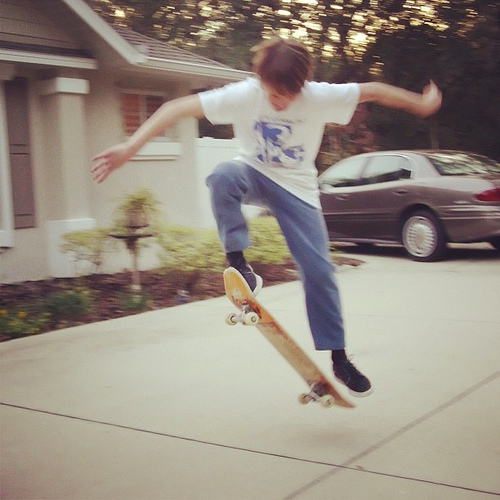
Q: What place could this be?
A: It is a sidewalk.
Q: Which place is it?
A: It is a sidewalk.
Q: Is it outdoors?
A: Yes, it is outdoors.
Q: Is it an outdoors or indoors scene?
A: It is outdoors.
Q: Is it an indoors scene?
A: No, it is outdoors.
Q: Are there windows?
A: Yes, there is a window.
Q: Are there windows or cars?
A: Yes, there is a window.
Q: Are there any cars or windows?
A: Yes, there is a window.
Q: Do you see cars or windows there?
A: Yes, there is a window.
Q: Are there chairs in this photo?
A: No, there are no chairs.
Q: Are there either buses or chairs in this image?
A: No, there are no chairs or buses.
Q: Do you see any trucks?
A: No, there are no trucks.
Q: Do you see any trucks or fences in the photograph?
A: No, there are no trucks or fences.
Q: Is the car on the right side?
A: Yes, the car is on the right of the image.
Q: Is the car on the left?
A: No, the car is on the right of the image.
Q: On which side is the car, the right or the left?
A: The car is on the right of the image.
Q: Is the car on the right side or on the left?
A: The car is on the right of the image.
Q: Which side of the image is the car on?
A: The car is on the right of the image.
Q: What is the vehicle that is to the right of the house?
A: The vehicle is a car.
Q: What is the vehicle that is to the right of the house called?
A: The vehicle is a car.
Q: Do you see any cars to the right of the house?
A: Yes, there is a car to the right of the house.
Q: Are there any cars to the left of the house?
A: No, the car is to the right of the house.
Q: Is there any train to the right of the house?
A: No, there is a car to the right of the house.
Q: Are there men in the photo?
A: No, there are no men.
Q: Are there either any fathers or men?
A: No, there are no men or fathers.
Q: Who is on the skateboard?
A: The boy is on the skateboard.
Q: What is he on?
A: The boy is on the skateboard.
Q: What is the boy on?
A: The boy is on the skateboard.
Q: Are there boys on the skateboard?
A: Yes, there is a boy on the skateboard.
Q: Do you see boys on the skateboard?
A: Yes, there is a boy on the skateboard.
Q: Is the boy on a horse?
A: No, the boy is on the skateboard.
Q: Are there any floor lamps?
A: No, there are no floor lamps.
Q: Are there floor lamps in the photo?
A: No, there are no floor lamps.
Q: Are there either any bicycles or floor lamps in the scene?
A: No, there are no floor lamps or bicycles.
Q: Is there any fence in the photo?
A: No, there are no fences.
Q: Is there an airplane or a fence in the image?
A: No, there are no fences or airplanes.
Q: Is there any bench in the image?
A: No, there are no benches.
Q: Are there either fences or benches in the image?
A: No, there are no benches or fences.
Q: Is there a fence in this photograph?
A: No, there are no fences.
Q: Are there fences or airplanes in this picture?
A: No, there are no fences or airplanes.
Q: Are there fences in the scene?
A: No, there are no fences.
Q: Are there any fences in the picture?
A: No, there are no fences.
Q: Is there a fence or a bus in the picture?
A: No, there are no fences or buses.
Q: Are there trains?
A: No, there are no trains.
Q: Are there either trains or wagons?
A: No, there are no trains or wagons.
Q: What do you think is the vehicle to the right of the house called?
A: The vehicle is a car.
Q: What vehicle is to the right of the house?
A: The vehicle is a car.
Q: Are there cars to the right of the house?
A: Yes, there is a car to the right of the house.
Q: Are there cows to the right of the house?
A: No, there is a car to the right of the house.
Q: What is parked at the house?
A: The car is parked at the house.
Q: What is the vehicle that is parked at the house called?
A: The vehicle is a car.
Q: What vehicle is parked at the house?
A: The vehicle is a car.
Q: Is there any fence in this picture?
A: No, there are no fences.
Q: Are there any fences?
A: No, there are no fences.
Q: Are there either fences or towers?
A: No, there are no fences or towers.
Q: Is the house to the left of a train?
A: No, the house is to the left of the car.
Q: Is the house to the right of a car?
A: No, the house is to the left of a car.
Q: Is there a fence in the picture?
A: No, there are no fences.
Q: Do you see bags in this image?
A: No, there are no bags.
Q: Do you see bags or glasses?
A: No, there are no bags or glasses.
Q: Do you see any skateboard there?
A: Yes, there is a skateboard.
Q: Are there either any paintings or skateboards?
A: Yes, there is a skateboard.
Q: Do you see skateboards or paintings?
A: Yes, there is a skateboard.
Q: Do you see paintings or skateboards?
A: Yes, there is a skateboard.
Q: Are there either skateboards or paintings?
A: Yes, there is a skateboard.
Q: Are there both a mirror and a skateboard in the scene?
A: No, there is a skateboard but no mirrors.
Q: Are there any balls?
A: No, there are no balls.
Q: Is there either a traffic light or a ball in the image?
A: No, there are no balls or traffic lights.